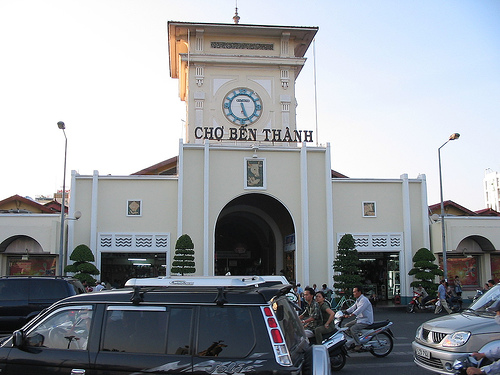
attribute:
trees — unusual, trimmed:
[328, 222, 451, 313]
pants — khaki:
[433, 300, 453, 316]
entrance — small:
[354, 257, 404, 303]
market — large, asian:
[175, 139, 353, 306]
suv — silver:
[426, 280, 498, 370]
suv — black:
[1, 277, 333, 372]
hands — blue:
[234, 99, 245, 117]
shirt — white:
[343, 296, 378, 331]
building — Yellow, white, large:
[49, 10, 463, 315]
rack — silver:
[123, 265, 273, 295]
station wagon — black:
[19, 242, 373, 373]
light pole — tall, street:
[54, 117, 70, 276]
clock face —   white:
[218, 84, 265, 129]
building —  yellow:
[159, 10, 337, 192]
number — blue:
[238, 85, 247, 97]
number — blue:
[246, 87, 253, 98]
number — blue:
[253, 97, 263, 106]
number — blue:
[254, 102, 262, 111]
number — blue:
[248, 110, 260, 119]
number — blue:
[243, 115, 255, 127]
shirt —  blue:
[434, 283, 449, 302]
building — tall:
[483, 163, 498, 212]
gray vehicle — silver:
[408, 287, 499, 372]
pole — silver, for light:
[51, 118, 71, 278]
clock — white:
[221, 85, 261, 128]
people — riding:
[278, 278, 395, 369]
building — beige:
[2, 7, 498, 306]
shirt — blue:
[340, 293, 378, 323]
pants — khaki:
[339, 320, 369, 338]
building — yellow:
[66, 13, 432, 305]